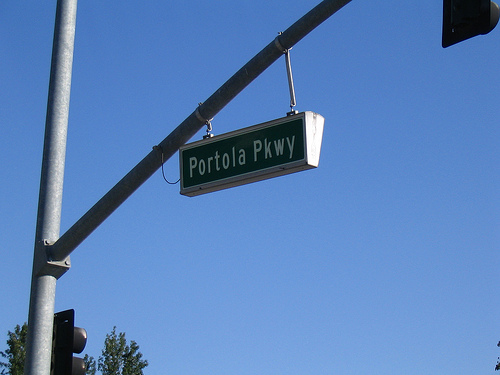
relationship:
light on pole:
[50, 307, 89, 373] [24, 3, 78, 373]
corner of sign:
[295, 139, 324, 174] [170, 104, 335, 205]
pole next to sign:
[40, 6, 333, 283] [170, 104, 335, 205]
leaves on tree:
[100, 342, 118, 361] [93, 324, 153, 373]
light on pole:
[50, 305, 97, 373] [24, 3, 93, 373]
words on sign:
[184, 141, 249, 178] [170, 104, 335, 205]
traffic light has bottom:
[437, 3, 498, 50] [435, 24, 496, 51]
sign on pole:
[178, 111, 323, 199] [77, 24, 362, 142]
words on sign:
[184, 146, 245, 177] [170, 104, 335, 205]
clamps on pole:
[270, 31, 295, 54] [235, 8, 331, 73]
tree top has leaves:
[92, 321, 157, 373] [113, 339, 125, 348]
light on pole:
[50, 307, 89, 373] [21, 1, 62, 370]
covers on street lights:
[72, 321, 90, 355] [50, 306, 97, 373]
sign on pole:
[170, 104, 335, 205] [135, 30, 344, 131]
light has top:
[50, 307, 89, 373] [53, 308, 91, 342]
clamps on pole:
[197, 35, 304, 138] [182, 30, 309, 124]